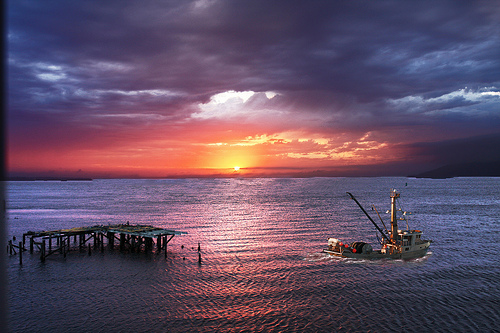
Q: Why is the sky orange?
A: The sun is setting.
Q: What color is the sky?
A: Orange.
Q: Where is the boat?
A: In the water.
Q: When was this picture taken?
A: At sunset.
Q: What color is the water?
A: Purple.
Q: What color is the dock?
A: Brown.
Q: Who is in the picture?
A: No one.